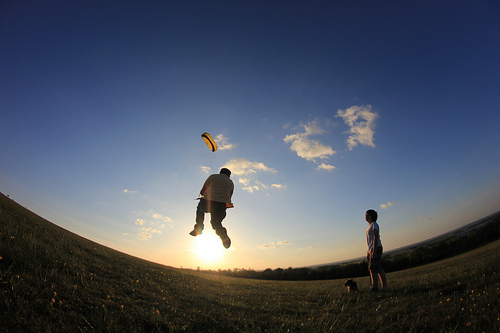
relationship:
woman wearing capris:
[368, 195, 385, 287] [355, 259, 406, 285]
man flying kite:
[194, 186, 242, 241] [197, 128, 232, 148]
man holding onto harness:
[194, 186, 242, 241] [198, 164, 222, 172]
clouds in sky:
[280, 134, 345, 177] [24, 23, 88, 54]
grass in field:
[264, 302, 310, 314] [35, 235, 94, 282]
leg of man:
[175, 208, 208, 221] [194, 186, 242, 241]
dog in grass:
[341, 280, 360, 292] [264, 302, 310, 314]